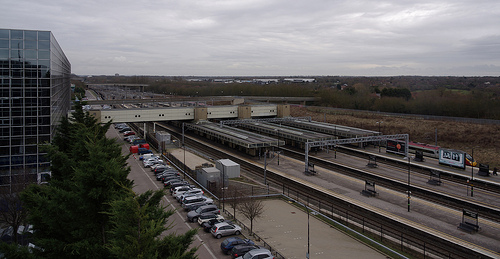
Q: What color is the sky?
A: Gray.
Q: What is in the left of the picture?
A: A building.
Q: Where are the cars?
A: In the parking lot.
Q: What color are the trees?
A: Green.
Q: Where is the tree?
A: By the building.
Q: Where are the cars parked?
A: In the parking area.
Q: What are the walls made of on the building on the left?
A: Windows.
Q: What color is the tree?
A: Green.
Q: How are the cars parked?
A: In a row.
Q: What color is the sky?
A: Grey.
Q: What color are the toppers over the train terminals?
A: White.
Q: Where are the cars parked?
A: By the gate.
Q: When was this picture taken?
A: In the daytime.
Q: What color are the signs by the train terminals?
A: Black and White.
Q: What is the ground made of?
A: Cement.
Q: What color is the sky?
A: Gray.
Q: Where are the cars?
A: In the parking lot.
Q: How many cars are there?
A: Large number.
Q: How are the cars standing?
A: In line.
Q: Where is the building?
A: On the left.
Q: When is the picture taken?
A: Day time.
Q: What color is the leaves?
A: Green.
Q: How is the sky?
A: Cloudy.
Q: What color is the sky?
A: White.